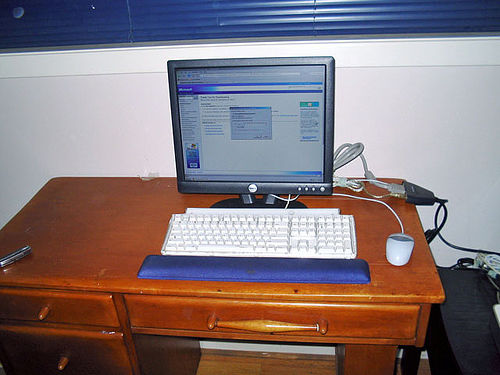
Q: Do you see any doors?
A: Yes, there is a door.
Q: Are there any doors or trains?
A: Yes, there is a door.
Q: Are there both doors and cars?
A: No, there is a door but no cars.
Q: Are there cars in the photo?
A: No, there are no cars.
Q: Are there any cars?
A: No, there are no cars.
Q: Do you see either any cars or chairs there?
A: No, there are no cars or chairs.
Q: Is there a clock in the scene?
A: No, there are no clocks.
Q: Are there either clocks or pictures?
A: No, there are no clocks or pictures.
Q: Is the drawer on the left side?
A: Yes, the drawer is on the left of the image.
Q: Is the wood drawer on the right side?
A: No, the drawer is on the left of the image.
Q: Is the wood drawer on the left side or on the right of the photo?
A: The drawer is on the left of the image.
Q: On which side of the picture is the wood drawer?
A: The drawer is on the left of the image.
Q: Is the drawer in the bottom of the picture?
A: Yes, the drawer is in the bottom of the image.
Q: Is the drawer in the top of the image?
A: No, the drawer is in the bottom of the image.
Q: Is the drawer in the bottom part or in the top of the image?
A: The drawer is in the bottom of the image.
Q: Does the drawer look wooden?
A: Yes, the drawer is wooden.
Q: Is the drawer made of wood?
A: Yes, the drawer is made of wood.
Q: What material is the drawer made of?
A: The drawer is made of wood.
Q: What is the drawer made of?
A: The drawer is made of wood.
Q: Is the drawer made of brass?
A: No, the drawer is made of wood.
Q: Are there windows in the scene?
A: Yes, there is a window.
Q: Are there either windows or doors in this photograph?
A: Yes, there is a window.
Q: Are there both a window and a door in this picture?
A: Yes, there are both a window and a door.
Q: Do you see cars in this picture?
A: No, there are no cars.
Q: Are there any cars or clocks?
A: No, there are no cars or clocks.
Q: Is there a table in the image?
A: Yes, there is a table.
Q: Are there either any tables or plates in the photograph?
A: Yes, there is a table.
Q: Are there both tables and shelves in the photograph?
A: No, there is a table but no shelves.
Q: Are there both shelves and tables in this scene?
A: No, there is a table but no shelves.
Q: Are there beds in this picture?
A: No, there are no beds.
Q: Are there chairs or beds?
A: No, there are no beds or chairs.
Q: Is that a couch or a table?
A: That is a table.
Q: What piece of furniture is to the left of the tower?
A: The piece of furniture is a table.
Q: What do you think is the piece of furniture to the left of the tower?
A: The piece of furniture is a table.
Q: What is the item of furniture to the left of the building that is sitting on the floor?
A: The piece of furniture is a table.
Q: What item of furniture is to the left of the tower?
A: The piece of furniture is a table.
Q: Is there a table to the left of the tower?
A: Yes, there is a table to the left of the tower.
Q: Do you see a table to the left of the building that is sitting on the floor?
A: Yes, there is a table to the left of the tower.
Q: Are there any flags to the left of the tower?
A: No, there is a table to the left of the tower.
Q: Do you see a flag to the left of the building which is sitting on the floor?
A: No, there is a table to the left of the tower.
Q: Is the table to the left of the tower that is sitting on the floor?
A: Yes, the table is to the left of the tower.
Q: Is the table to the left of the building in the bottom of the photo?
A: Yes, the table is to the left of the tower.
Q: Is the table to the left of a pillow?
A: No, the table is to the left of the tower.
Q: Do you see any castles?
A: No, there are no castles.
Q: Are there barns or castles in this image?
A: No, there are no castles or barns.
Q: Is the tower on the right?
A: Yes, the tower is on the right of the image.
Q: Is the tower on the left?
A: No, the tower is on the right of the image.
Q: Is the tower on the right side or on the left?
A: The tower is on the right of the image.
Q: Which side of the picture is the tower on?
A: The tower is on the right of the image.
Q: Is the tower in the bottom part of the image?
A: Yes, the tower is in the bottom of the image.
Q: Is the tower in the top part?
A: No, the tower is in the bottom of the image.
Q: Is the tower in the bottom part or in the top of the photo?
A: The tower is in the bottom of the image.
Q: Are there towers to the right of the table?
A: Yes, there is a tower to the right of the table.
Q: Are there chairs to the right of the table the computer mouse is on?
A: No, there is a tower to the right of the table.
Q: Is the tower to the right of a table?
A: Yes, the tower is to the right of a table.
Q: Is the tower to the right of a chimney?
A: No, the tower is to the right of a table.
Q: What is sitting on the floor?
A: The tower is sitting on the floor.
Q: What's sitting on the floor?
A: The tower is sitting on the floor.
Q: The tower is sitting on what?
A: The tower is sitting on the floor.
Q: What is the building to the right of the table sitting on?
A: The tower is sitting on the floor.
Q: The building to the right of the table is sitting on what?
A: The tower is sitting on the floor.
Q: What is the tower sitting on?
A: The tower is sitting on the floor.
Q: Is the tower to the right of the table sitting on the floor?
A: Yes, the tower is sitting on the floor.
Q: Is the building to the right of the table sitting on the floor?
A: Yes, the tower is sitting on the floor.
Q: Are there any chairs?
A: No, there are no chairs.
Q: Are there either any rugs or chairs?
A: No, there are no chairs or rugs.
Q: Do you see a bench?
A: No, there are no benches.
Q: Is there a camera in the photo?
A: No, there are no cameras.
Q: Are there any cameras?
A: No, there are no cameras.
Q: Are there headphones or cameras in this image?
A: No, there are no cameras or headphones.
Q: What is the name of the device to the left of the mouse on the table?
A: The device is a desktop computer.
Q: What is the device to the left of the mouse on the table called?
A: The device is a desktop computer.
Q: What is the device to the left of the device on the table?
A: The device is a desktop computer.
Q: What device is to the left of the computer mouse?
A: The device is a desktop computer.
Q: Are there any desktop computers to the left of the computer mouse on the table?
A: Yes, there is a desktop computer to the left of the mouse.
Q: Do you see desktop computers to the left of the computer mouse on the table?
A: Yes, there is a desktop computer to the left of the mouse.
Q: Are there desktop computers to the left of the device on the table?
A: Yes, there is a desktop computer to the left of the mouse.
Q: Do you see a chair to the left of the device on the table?
A: No, there is a desktop computer to the left of the mouse.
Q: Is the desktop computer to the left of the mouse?
A: Yes, the desktop computer is to the left of the mouse.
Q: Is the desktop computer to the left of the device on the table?
A: Yes, the desktop computer is to the left of the mouse.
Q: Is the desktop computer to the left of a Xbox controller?
A: No, the desktop computer is to the left of the mouse.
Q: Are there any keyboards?
A: Yes, there is a keyboard.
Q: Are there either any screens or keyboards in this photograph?
A: Yes, there is a keyboard.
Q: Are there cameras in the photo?
A: No, there are no cameras.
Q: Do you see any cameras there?
A: No, there are no cameras.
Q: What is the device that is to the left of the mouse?
A: The device is a keyboard.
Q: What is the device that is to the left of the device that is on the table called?
A: The device is a keyboard.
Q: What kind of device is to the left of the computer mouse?
A: The device is a keyboard.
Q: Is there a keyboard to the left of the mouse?
A: Yes, there is a keyboard to the left of the mouse.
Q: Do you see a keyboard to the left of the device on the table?
A: Yes, there is a keyboard to the left of the mouse.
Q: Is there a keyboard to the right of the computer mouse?
A: No, the keyboard is to the left of the computer mouse.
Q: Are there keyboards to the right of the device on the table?
A: No, the keyboard is to the left of the computer mouse.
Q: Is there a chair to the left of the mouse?
A: No, there is a keyboard to the left of the mouse.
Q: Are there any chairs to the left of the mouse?
A: No, there is a keyboard to the left of the mouse.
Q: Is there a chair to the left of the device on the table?
A: No, there is a keyboard to the left of the mouse.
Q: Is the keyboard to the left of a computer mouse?
A: Yes, the keyboard is to the left of a computer mouse.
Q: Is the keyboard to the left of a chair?
A: No, the keyboard is to the left of a computer mouse.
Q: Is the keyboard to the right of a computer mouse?
A: No, the keyboard is to the left of a computer mouse.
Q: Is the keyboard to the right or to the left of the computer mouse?
A: The keyboard is to the left of the computer mouse.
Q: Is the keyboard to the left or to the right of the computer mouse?
A: The keyboard is to the left of the computer mouse.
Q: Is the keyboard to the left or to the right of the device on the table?
A: The keyboard is to the left of the computer mouse.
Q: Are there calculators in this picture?
A: No, there are no calculators.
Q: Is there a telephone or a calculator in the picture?
A: No, there are no calculators or phones.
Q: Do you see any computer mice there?
A: Yes, there is a computer mouse.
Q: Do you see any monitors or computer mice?
A: Yes, there is a computer mouse.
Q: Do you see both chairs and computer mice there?
A: No, there is a computer mouse but no chairs.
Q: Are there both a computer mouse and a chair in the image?
A: No, there is a computer mouse but no chairs.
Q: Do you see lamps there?
A: No, there are no lamps.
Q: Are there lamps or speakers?
A: No, there are no lamps or speakers.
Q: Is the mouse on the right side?
A: Yes, the mouse is on the right of the image.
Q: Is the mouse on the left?
A: No, the mouse is on the right of the image.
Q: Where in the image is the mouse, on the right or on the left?
A: The mouse is on the right of the image.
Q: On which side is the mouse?
A: The mouse is on the right of the image.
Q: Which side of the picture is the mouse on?
A: The mouse is on the right of the image.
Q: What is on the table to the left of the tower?
A: The mouse is on the table.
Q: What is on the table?
A: The mouse is on the table.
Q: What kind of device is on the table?
A: The device is a computer mouse.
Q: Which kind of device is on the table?
A: The device is a computer mouse.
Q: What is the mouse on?
A: The mouse is on the table.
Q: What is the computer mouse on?
A: The mouse is on the table.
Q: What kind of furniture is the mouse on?
A: The mouse is on the table.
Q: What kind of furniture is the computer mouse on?
A: The mouse is on the table.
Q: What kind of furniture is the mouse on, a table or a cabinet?
A: The mouse is on a table.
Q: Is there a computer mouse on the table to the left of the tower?
A: Yes, there is a computer mouse on the table.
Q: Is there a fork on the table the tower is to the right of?
A: No, there is a computer mouse on the table.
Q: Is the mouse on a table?
A: Yes, the mouse is on a table.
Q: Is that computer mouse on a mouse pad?
A: No, the computer mouse is on a table.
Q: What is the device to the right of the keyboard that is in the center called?
A: The device is a computer mouse.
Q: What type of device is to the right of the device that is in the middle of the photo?
A: The device is a computer mouse.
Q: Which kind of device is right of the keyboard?
A: The device is a computer mouse.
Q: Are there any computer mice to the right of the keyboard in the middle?
A: Yes, there is a computer mouse to the right of the keyboard.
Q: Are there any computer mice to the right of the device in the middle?
A: Yes, there is a computer mouse to the right of the keyboard.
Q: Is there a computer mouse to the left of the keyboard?
A: No, the computer mouse is to the right of the keyboard.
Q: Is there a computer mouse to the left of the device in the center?
A: No, the computer mouse is to the right of the keyboard.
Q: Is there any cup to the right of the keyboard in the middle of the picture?
A: No, there is a computer mouse to the right of the keyboard.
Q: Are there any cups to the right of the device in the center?
A: No, there is a computer mouse to the right of the keyboard.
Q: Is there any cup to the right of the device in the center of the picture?
A: No, there is a computer mouse to the right of the keyboard.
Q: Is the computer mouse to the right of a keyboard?
A: Yes, the computer mouse is to the right of a keyboard.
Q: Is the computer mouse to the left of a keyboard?
A: No, the computer mouse is to the right of a keyboard.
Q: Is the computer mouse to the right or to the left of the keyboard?
A: The computer mouse is to the right of the keyboard.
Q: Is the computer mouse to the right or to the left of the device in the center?
A: The computer mouse is to the right of the keyboard.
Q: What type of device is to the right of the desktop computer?
A: The device is a computer mouse.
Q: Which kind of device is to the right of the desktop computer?
A: The device is a computer mouse.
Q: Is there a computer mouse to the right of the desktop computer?
A: Yes, there is a computer mouse to the right of the desktop computer.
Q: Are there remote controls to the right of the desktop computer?
A: No, there is a computer mouse to the right of the desktop computer.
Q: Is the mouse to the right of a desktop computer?
A: Yes, the mouse is to the right of a desktop computer.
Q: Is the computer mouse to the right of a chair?
A: No, the computer mouse is to the right of a desktop computer.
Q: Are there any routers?
A: No, there are no routers.